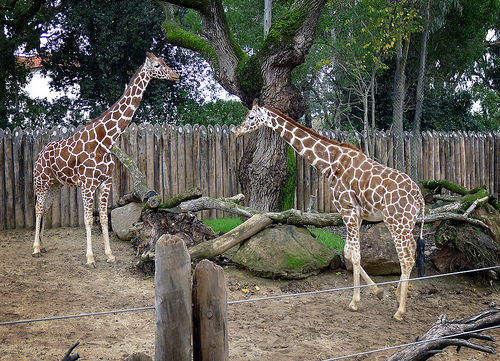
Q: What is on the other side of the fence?
A: Trees.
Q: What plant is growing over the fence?
A: Tall trees.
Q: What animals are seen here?
A: Two giraffes.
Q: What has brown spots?
A: Giraffe.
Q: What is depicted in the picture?
A: Two giraffes.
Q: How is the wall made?
A: Wooden.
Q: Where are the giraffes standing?
A: In front of the tree.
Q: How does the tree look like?
A: Thick and rough.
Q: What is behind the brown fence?
A: A tall white building.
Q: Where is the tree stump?
A: On the stone.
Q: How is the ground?
A: Brown and dirty.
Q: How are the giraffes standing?
A: Face to face.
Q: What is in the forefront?
A: A wood post and wire fence.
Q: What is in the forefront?
A: A wire fence.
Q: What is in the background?
A: A log and a rock.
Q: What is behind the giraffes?
A: A wood fence.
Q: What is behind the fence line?
A: Trees are behind the fence.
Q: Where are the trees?
A: Inside the enclosure.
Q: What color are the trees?
A: Green.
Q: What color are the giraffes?
A: Brown and white.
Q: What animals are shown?
A: Giraffes.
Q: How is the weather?
A: Clear.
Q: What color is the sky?
A: Blue.